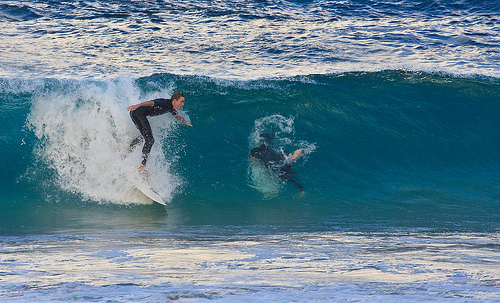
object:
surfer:
[119, 91, 192, 179]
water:
[185, 136, 233, 200]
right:
[153, 90, 200, 111]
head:
[170, 92, 187, 110]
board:
[118, 146, 169, 207]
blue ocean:
[326, 96, 499, 186]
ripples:
[27, 108, 30, 114]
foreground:
[0, 182, 311, 295]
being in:
[143, 79, 339, 195]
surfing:
[101, 145, 203, 184]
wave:
[181, 145, 185, 147]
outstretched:
[130, 88, 187, 130]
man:
[122, 91, 194, 179]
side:
[125, 96, 171, 128]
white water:
[53, 86, 131, 200]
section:
[202, 99, 244, 125]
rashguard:
[127, 110, 160, 164]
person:
[245, 118, 317, 197]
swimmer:
[246, 127, 314, 197]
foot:
[286, 148, 306, 162]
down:
[245, 114, 312, 173]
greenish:
[392, 89, 469, 158]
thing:
[235, 119, 277, 148]